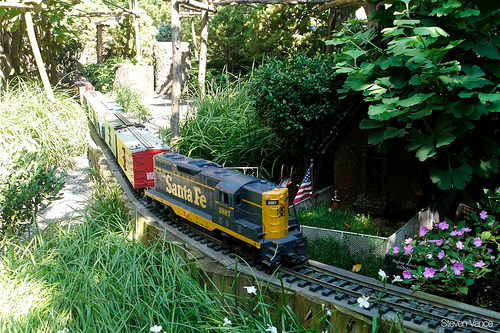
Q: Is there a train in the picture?
A: Yes, there is a train.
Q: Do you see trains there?
A: Yes, there is a train.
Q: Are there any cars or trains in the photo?
A: Yes, there is a train.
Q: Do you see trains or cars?
A: Yes, there is a train.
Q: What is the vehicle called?
A: The vehicle is a train.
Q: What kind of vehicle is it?
A: The vehicle is a train.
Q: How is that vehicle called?
A: That is a train.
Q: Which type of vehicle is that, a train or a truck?
A: That is a train.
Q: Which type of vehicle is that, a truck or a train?
A: That is a train.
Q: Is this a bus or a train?
A: This is a train.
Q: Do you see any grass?
A: Yes, there is grass.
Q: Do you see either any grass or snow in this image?
A: Yes, there is grass.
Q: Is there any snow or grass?
A: Yes, there is grass.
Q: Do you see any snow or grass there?
A: Yes, there is grass.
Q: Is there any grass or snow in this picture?
A: Yes, there is grass.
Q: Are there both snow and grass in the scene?
A: No, there is grass but no snow.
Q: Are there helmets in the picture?
A: No, there are no helmets.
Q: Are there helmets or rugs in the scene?
A: No, there are no helmets or rugs.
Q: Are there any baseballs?
A: No, there are no baseballs.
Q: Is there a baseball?
A: No, there are no baseballs.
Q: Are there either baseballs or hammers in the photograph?
A: No, there are no baseballs or hammers.